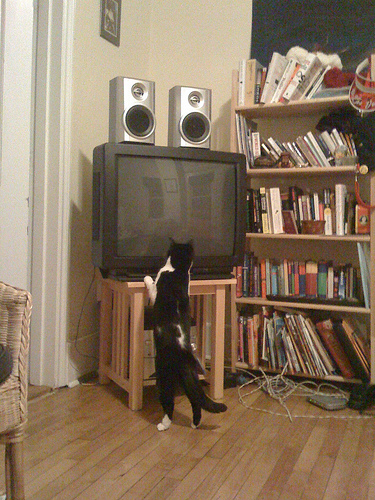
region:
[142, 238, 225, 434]
black and white cat looking at tv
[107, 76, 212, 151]
two speakers on the tv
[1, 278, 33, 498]
side of a chair made of straw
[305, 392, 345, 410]
modem for internet access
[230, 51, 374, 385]
bookcase full of books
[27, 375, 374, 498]
floor made of wood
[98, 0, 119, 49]
framed picture on the wall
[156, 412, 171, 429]
white left paw of the cat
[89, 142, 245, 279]
large black tv on a table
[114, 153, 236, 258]
room reflection on tv screen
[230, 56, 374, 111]
The shelf is cluttered.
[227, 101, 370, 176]
The shelf is cluttered.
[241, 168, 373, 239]
The shelf is full.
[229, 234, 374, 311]
The shelf is full.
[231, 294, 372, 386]
The shelf is full.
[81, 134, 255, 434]
The cat is climbing up the tv stand.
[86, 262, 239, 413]
The tv stand is wood.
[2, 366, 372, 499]
The floor is hardwood.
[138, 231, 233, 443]
The cat is black and white.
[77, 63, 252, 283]
Two speakers are on top of the tv.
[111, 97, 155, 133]
Silver speaker on top of television.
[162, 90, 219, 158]
Silver speaker on top of television.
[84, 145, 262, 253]
Black television on top of stand.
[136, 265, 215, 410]
Cat's front paws up on tv stand.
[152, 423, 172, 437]
Cat has white back paw.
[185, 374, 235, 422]
Cat has black tail.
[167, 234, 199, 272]
Cat has black head.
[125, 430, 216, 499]
Light brown wood floor in room.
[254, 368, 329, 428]
Cords laying on floor.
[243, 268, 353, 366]
Many books on shelf.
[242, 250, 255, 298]
Small books on a book case shelf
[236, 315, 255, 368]
Small books on a book case shelf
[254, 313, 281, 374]
Small books on a book case shelf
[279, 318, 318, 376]
Small books on a book case shelf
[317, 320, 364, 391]
Small books on a book case shelf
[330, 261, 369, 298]
Small books on a book case shelf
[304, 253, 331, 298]
Small books on a book case shelf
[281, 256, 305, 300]
Small books on a book case shelf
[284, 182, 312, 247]
Small books on a book case shelf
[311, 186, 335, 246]
Small books on a book case shelf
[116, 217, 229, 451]
Cat looking at the television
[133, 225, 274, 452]
The cat is black and white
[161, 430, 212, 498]
Floor is made of wood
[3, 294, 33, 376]
Furniture is made of wicker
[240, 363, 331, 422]
Rope on the floor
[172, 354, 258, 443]
Cat has a black tail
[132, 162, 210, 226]
Reflection on the tv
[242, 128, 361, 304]
Books in the bookcase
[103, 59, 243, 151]
Speakers on top of the television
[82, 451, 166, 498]
Wood planks on the floor